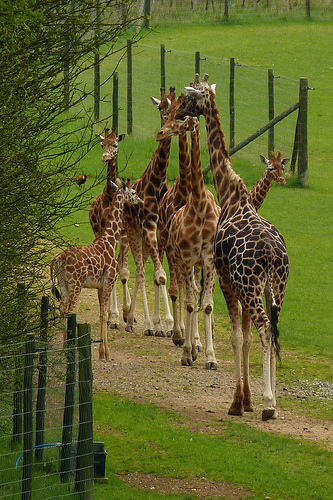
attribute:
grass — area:
[167, 435, 297, 480]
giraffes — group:
[58, 35, 332, 315]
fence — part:
[83, 40, 312, 172]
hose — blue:
[10, 440, 60, 479]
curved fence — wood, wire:
[7, 289, 99, 496]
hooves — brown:
[223, 384, 280, 422]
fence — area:
[1, 338, 111, 498]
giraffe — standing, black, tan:
[174, 72, 290, 420]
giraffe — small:
[48, 171, 143, 345]